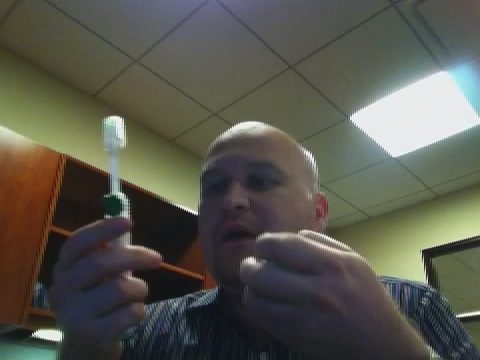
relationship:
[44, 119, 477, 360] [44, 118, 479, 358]
man holding toothbrush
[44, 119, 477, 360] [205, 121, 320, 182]
man with bald head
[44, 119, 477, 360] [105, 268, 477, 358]
man wearing shirt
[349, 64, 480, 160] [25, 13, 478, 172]
light on ceiling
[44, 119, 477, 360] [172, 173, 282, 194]
man with eyes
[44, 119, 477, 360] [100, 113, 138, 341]
man holding white stick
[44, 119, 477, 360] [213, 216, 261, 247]
man with mouth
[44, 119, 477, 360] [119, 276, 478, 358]
man wearing shirt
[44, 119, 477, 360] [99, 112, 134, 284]
man holding tooth brush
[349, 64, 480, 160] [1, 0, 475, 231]
light on ceiling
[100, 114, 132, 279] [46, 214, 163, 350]
toothbrush in hand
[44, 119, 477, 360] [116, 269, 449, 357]
man wearing shirt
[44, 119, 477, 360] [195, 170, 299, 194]
man has eyes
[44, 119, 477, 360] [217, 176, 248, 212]
man has nose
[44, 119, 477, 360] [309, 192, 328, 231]
man has left ear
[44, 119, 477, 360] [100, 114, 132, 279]
man looking at toothbrush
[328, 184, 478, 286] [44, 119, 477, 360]
wall behind man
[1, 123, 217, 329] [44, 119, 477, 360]
cabinet behind man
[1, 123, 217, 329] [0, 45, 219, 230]
cabinet on wall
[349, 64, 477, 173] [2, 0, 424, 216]
light on ceiling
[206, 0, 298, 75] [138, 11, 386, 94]
trim on ceiling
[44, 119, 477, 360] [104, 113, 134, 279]
man holding toothbrush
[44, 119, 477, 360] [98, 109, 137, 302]
man looking at toothbrush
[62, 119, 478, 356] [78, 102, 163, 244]
man holding toothbrush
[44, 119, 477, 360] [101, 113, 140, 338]
man looking at toothbrush